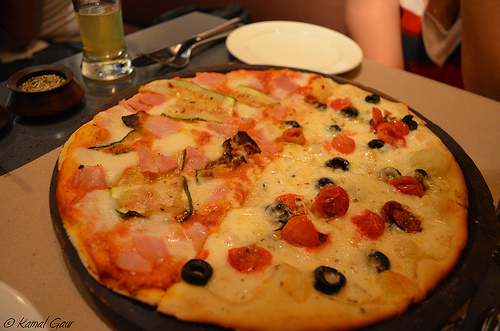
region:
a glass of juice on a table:
[71, 1, 133, 79]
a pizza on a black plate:
[55, 68, 467, 329]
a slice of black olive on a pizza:
[316, 263, 343, 295]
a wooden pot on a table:
[6, 60, 84, 124]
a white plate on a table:
[224, 16, 362, 74]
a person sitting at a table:
[343, 0, 499, 100]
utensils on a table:
[133, 18, 243, 70]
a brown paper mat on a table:
[0, 58, 499, 326]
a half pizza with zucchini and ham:
[55, 68, 338, 303]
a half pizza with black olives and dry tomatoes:
[159, 83, 467, 327]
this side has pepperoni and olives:
[216, 102, 433, 299]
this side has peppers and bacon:
[62, 55, 313, 275]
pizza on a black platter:
[106, 85, 451, 298]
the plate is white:
[230, 24, 353, 69]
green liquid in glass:
[80, 0, 122, 62]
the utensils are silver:
[151, 18, 242, 87]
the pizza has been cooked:
[23, 58, 444, 309]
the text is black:
[0, 314, 74, 327]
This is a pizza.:
[53, 62, 472, 321]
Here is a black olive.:
[317, 263, 349, 295]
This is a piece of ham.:
[129, 139, 171, 178]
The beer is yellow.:
[58, 0, 133, 82]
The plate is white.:
[225, 11, 371, 74]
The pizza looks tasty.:
[58, 62, 473, 318]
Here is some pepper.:
[13, 65, 80, 113]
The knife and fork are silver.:
[128, 13, 254, 68]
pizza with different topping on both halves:
[56, 68, 472, 329]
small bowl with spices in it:
[6, 63, 81, 127]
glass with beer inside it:
[71, 0, 135, 80]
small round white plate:
[225, 19, 360, 76]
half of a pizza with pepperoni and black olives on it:
[166, 83, 467, 327]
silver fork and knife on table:
[131, 18, 239, 68]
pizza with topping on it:
[56, 69, 471, 330]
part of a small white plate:
[0, 282, 47, 329]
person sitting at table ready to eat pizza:
[344, 2, 499, 102]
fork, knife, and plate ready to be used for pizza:
[132, 16, 362, 75]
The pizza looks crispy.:
[53, 68, 473, 320]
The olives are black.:
[178, 256, 218, 286]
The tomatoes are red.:
[279, 216, 322, 249]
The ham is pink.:
[132, 110, 184, 137]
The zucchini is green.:
[144, 76, 238, 124]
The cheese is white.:
[57, 65, 461, 318]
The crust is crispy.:
[193, 291, 347, 322]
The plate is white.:
[0, 276, 53, 327]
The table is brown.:
[425, 86, 492, 126]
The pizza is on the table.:
[40, 66, 477, 321]